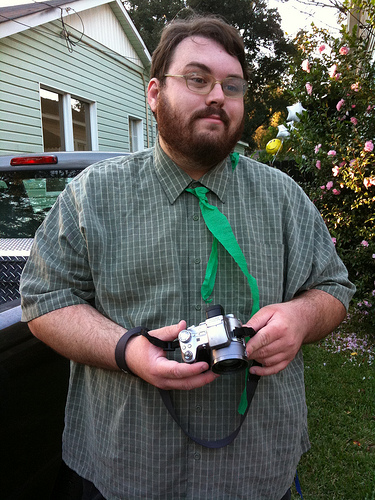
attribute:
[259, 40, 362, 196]
rose tree — pink 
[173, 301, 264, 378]
camera — grey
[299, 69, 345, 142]
roses — pink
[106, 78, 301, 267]
man — wearing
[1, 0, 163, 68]
roof top — white, black, green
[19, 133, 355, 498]
shirt — green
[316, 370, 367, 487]
grass — green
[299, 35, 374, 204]
flowers — pink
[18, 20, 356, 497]
man — smiling, holding, wearing, white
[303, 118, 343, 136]
bush — dark green 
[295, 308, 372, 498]
grass — green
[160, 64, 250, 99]
glasses — clear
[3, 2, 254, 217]
house — green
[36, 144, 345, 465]
shirt — grey, striped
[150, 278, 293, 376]
camera — grey, digital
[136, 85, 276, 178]
beard — brown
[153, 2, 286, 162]
tree — tall